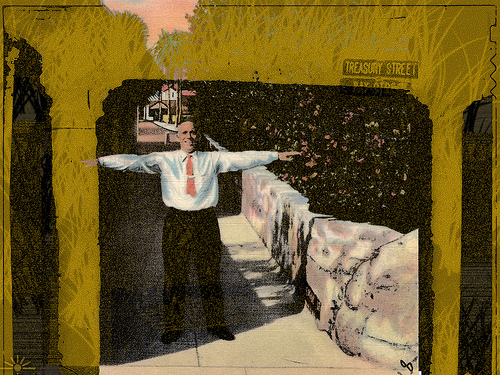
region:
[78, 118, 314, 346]
Man with limbs spread out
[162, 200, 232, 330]
Dark colored pair of pants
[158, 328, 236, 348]
Black pair of shoes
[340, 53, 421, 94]
Writing on the wall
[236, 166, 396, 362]
Low white painted wall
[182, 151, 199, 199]
Red tie with strapping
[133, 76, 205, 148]
Buildings in the background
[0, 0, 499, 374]
Yellow painted entrance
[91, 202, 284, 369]
Shadow on the ground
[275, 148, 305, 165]
Hand with fingers stretched straight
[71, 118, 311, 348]
Man with limbs spead out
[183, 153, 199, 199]
Red tie with a clipping holder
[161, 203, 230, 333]
Dark pair of pants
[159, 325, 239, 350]
Dark black pair of shoes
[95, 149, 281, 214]
Very white colored shirt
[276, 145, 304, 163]
Hand with fingers straightened out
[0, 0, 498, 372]
Yellow bands forming a frame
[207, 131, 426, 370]
Low wall painted white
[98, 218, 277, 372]
Shadow falling on the ground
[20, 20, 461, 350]
the picture is old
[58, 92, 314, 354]
this man resembles the actor Eliot Gould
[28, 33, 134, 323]
a yellow support beam on the building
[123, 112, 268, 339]
he is standing on a bridge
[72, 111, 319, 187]
his hands are extended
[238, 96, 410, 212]
leaves in the area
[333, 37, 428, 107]
a sign designating a street name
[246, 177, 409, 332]
a brick guard rail for the bridge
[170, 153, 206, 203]
he is wearing a short tie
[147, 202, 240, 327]
this man has on brown pants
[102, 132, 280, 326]
A man standing in a tie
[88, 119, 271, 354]
A man standing in a white shirt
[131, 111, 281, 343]
A man standing in black trousers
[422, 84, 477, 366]
A yellow house wall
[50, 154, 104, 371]
A yellow house wall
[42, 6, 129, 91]
A yellow house wall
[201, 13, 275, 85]
A yellow house wall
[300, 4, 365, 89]
A yellow house wall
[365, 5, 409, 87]
A yellow house wall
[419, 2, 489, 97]
A yellow house wall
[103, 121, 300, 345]
man with extended arms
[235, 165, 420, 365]
stone wall with shadows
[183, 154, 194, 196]
red tie on shirt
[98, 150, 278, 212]
long sleeved white shirt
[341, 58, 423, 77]
two words on street sign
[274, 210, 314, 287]
shadows on stone wall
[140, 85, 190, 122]
front of house in the distance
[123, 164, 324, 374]
flat surface of walkway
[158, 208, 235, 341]
dark pants and shoes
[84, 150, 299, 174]
two extended arms of man